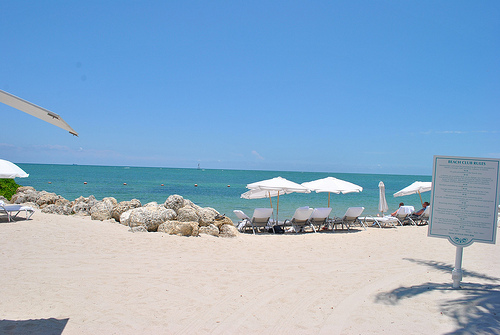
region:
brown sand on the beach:
[182, 252, 297, 318]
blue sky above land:
[176, 48, 262, 113]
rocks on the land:
[147, 179, 210, 242]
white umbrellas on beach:
[246, 148, 363, 225]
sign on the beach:
[415, 133, 494, 243]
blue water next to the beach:
[118, 159, 175, 207]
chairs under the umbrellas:
[286, 198, 329, 243]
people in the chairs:
[387, 195, 430, 227]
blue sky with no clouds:
[155, 31, 307, 117]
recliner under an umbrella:
[1, 156, 61, 235]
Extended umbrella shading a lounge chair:
[304, 174, 369, 201]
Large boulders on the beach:
[110, 195, 237, 247]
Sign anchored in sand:
[428, 153, 498, 243]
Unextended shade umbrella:
[375, 181, 388, 218]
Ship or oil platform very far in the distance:
[192, 159, 205, 171]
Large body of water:
[137, 168, 156, 198]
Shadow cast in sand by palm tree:
[437, 291, 491, 333]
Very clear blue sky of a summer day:
[225, 44, 320, 116]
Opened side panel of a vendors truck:
[0, 68, 84, 158]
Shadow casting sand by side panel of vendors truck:
[0, 298, 81, 334]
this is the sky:
[168, 49, 427, 118]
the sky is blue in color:
[173, 48, 324, 99]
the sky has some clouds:
[108, 150, 172, 166]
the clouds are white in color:
[87, 150, 145, 163]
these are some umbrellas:
[241, 175, 371, 216]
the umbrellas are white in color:
[273, 177, 342, 192]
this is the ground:
[48, 257, 286, 304]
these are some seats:
[248, 209, 363, 231]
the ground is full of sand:
[75, 255, 256, 313]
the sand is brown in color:
[186, 259, 286, 304]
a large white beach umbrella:
[249, 173, 302, 197]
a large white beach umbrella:
[242, 181, 295, 200]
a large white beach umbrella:
[302, 174, 357, 198]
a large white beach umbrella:
[395, 177, 432, 200]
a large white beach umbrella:
[1, 157, 28, 185]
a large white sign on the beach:
[431, 151, 494, 296]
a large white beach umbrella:
[375, 179, 390, 213]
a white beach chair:
[244, 203, 273, 233]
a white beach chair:
[283, 206, 313, 233]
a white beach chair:
[310, 207, 333, 231]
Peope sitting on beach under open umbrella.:
[385, 175, 432, 250]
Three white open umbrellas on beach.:
[238, 170, 368, 213]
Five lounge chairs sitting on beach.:
[233, 202, 370, 239]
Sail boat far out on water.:
[182, 155, 219, 177]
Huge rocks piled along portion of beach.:
[50, 191, 235, 249]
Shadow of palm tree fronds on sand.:
[371, 253, 492, 333]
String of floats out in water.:
[56, 174, 235, 190]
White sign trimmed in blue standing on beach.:
[423, 151, 499, 299]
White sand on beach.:
[133, 259, 355, 327]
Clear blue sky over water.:
[114, 29, 425, 127]